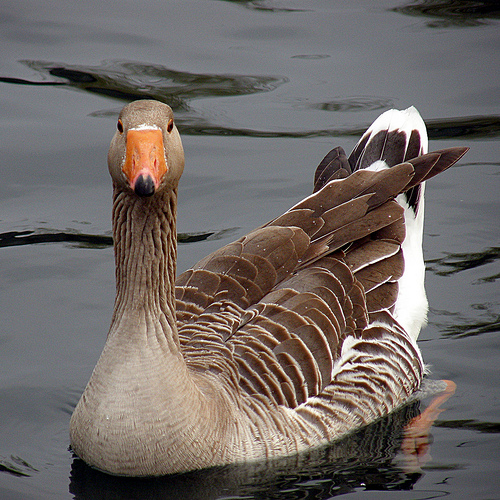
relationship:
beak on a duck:
[119, 126, 169, 197] [66, 99, 470, 478]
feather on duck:
[306, 189, 378, 245] [66, 96, 470, 478]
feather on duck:
[180, 176, 391, 369] [66, 96, 470, 478]